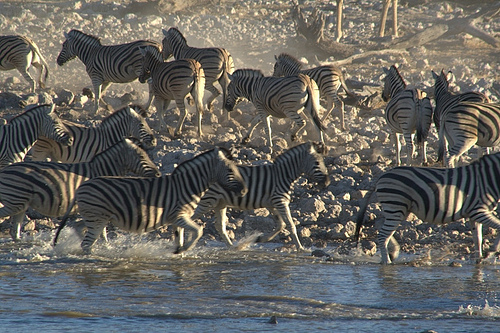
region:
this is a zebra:
[91, 173, 203, 247]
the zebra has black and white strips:
[107, 182, 159, 204]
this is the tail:
[354, 182, 367, 234]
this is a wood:
[318, 20, 478, 58]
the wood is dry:
[423, 14, 475, 44]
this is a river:
[100, 262, 294, 317]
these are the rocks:
[313, 192, 350, 240]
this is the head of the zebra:
[303, 147, 329, 195]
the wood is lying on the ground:
[309, 20, 459, 63]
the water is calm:
[36, 283, 131, 307]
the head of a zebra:
[294, 139, 337, 194]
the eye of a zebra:
[309, 157, 325, 169]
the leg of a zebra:
[271, 199, 304, 248]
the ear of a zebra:
[206, 142, 225, 158]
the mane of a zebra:
[168, 144, 215, 178]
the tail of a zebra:
[348, 179, 382, 249]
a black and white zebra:
[214, 64, 333, 146]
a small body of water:
[0, 241, 499, 331]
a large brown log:
[293, 7, 498, 64]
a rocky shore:
[0, 0, 497, 242]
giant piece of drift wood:
[292, 1, 499, 61]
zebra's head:
[207, 143, 250, 200]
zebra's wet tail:
[352, 179, 376, 244]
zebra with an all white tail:
[193, 71, 204, 109]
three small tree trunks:
[330, 0, 401, 43]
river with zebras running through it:
[1, 237, 498, 330]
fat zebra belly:
[412, 183, 465, 226]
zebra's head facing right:
[299, 140, 331, 189]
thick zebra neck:
[10, 107, 37, 157]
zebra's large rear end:
[170, 57, 206, 99]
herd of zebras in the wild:
[0, 25, 496, 265]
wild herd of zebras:
[0, 25, 497, 262]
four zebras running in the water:
[0, 137, 496, 262]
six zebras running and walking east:
[0, 100, 496, 265]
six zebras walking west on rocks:
[0, 25, 347, 150]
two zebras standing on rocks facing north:
[379, 64, 488, 166]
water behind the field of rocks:
[0, 265, 497, 331]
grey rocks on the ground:
[0, 0, 286, 27]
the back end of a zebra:
[0, 32, 49, 92]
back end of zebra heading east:
[438, 100, 498, 165]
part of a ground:
[317, 190, 356, 236]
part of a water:
[323, 257, 379, 318]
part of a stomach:
[242, 186, 269, 216]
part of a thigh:
[388, 215, 403, 271]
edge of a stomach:
[225, 197, 265, 226]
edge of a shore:
[323, 245, 360, 260]